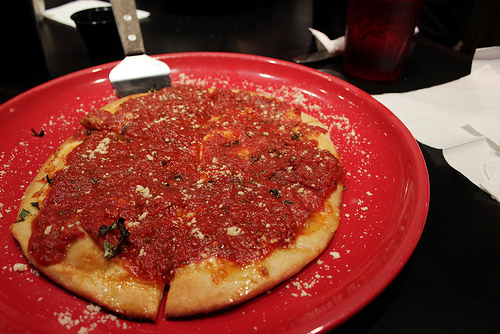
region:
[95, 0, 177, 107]
Pizza spatula with a wood handle.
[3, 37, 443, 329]
Large red, round plate.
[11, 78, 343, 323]
Small single serve pizza sitting on a plate.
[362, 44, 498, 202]
White napkin sitting on the table.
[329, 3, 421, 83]
Red cup sitting next to the napkin.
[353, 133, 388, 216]
Sprinkles of parmesan on the plate.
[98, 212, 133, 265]
Ribbon of cut basil for flavor on the pizza.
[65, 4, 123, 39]
Black ramiken for dipping sauce.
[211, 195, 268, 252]
Marinara sauce covering the delicious pizza.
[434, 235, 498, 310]
Very dark colored table.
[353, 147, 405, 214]
this is a plate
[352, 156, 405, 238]
the plate is red in color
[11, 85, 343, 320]
this is a pizza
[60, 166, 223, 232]
the pizza has some spices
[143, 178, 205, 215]
the spices are red in color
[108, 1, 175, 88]
this is a small spade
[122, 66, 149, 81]
the spade is metallic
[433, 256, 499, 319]
this is a table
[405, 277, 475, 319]
the table is black in color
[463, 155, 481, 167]
the cloth is white in color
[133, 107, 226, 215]
Red sauce on pizza.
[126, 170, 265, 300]
White cheese sprinkled on pizza.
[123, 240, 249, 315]
Pizza has golden brown crust.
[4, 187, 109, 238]
Seasoning on top of pizza.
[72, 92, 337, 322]
Pizza is cut into slices.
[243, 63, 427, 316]
Pizza is sitting on top of red plate.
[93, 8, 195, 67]
Spatula has wood handle.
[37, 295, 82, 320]
White cheese sprinkled on plate.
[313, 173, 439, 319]
Red plate sitting on black surface.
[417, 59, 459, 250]
White napkin on black surface.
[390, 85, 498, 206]
white tissue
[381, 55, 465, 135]
white tissue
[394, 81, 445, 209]
white tissue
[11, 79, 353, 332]
Tomato and basil pie on red plate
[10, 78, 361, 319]
Tomato and basil pie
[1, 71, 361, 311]
Crushed tomatoes on crust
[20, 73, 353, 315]
Baked crushed tomatoes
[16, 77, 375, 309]
tomatoe pizza on red plate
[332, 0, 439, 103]
red plastic cup on table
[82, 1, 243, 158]
Silver and wood pizza serving untensil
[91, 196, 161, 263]
red crushed tomatoe paste with green herb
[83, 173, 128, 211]
red crushed tomatoe paste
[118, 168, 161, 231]
parmasan cheese on crushed tomatoe paste